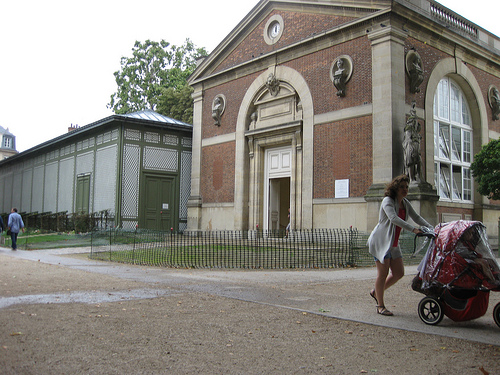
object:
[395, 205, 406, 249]
shirt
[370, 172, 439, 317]
woman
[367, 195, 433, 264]
sweater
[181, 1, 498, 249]
building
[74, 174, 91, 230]
door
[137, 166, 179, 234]
door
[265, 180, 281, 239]
door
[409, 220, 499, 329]
stroller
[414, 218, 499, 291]
plastic cover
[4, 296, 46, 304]
water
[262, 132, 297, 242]
table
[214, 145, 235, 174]
wall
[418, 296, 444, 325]
wheel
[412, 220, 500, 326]
cart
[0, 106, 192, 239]
building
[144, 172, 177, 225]
green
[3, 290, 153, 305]
puddle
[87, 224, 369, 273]
fence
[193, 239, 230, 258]
grass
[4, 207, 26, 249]
man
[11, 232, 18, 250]
black pants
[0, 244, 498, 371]
sidewalk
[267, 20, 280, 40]
clock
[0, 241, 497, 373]
street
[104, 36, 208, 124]
tree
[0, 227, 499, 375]
ground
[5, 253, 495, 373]
rocks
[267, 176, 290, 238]
door